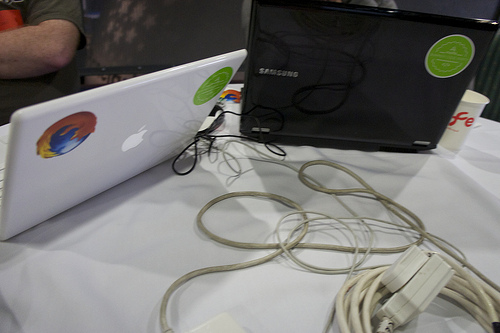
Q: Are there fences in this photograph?
A: No, there are no fences.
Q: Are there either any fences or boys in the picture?
A: No, there are no fences or boys.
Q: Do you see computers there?
A: Yes, there is a computer.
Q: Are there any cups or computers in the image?
A: Yes, there is a computer.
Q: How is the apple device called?
A: The device is a computer.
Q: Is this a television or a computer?
A: This is a computer.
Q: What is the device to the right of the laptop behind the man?
A: The device is a computer.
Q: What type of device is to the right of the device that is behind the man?
A: The device is a computer.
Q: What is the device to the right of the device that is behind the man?
A: The device is a computer.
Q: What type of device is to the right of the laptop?
A: The device is a computer.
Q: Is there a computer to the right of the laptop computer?
A: Yes, there is a computer to the right of the laptop computer.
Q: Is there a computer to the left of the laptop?
A: No, the computer is to the right of the laptop.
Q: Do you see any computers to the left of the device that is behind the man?
A: No, the computer is to the right of the laptop.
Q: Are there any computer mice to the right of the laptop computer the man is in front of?
A: No, there is a computer to the right of the laptop.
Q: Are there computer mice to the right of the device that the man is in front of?
A: No, there is a computer to the right of the laptop.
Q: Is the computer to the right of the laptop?
A: Yes, the computer is to the right of the laptop.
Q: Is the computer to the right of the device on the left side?
A: Yes, the computer is to the right of the laptop.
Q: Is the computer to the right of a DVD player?
A: No, the computer is to the right of the laptop.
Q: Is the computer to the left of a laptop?
A: No, the computer is to the right of a laptop.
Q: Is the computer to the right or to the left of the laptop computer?
A: The computer is to the right of the laptop computer.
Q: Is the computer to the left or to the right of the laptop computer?
A: The computer is to the right of the laptop computer.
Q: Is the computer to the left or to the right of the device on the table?
A: The computer is to the right of the laptop computer.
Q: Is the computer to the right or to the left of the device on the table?
A: The computer is to the right of the laptop computer.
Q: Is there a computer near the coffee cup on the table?
A: Yes, there is a computer near the coffee cup.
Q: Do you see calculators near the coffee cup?
A: No, there is a computer near the coffee cup.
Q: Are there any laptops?
A: Yes, there is a laptop.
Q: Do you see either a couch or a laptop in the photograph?
A: Yes, there is a laptop.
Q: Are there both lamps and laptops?
A: No, there is a laptop but no lamps.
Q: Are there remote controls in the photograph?
A: No, there are no remote controls.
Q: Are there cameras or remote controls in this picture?
A: No, there are no remote controls or cameras.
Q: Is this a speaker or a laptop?
A: This is a laptop.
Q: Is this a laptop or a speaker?
A: This is a laptop.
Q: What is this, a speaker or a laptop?
A: This is a laptop.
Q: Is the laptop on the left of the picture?
A: Yes, the laptop is on the left of the image.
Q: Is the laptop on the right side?
A: No, the laptop is on the left of the image.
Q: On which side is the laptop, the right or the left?
A: The laptop is on the left of the image.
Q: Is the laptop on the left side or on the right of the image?
A: The laptop is on the left of the image.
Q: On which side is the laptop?
A: The laptop is on the left of the image.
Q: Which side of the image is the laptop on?
A: The laptop is on the left of the image.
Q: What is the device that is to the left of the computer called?
A: The device is a laptop.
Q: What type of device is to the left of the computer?
A: The device is a laptop.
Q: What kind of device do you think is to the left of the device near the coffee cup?
A: The device is a laptop.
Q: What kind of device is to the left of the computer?
A: The device is a laptop.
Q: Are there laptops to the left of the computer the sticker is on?
A: Yes, there is a laptop to the left of the computer.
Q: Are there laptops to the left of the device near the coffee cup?
A: Yes, there is a laptop to the left of the computer.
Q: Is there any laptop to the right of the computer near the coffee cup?
A: No, the laptop is to the left of the computer.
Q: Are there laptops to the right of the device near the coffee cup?
A: No, the laptop is to the left of the computer.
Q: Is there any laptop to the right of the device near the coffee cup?
A: No, the laptop is to the left of the computer.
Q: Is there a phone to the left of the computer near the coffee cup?
A: No, there is a laptop to the left of the computer.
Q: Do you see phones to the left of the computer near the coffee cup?
A: No, there is a laptop to the left of the computer.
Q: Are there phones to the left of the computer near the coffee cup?
A: No, there is a laptop to the left of the computer.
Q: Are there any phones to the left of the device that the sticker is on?
A: No, there is a laptop to the left of the computer.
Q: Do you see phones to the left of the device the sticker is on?
A: No, there is a laptop to the left of the computer.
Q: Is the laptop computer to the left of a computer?
A: Yes, the laptop computer is to the left of a computer.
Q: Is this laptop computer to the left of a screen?
A: No, the laptop computer is to the left of a computer.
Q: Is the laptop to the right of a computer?
A: No, the laptop is to the left of a computer.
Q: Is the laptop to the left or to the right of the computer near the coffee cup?
A: The laptop is to the left of the computer.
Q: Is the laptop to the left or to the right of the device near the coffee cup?
A: The laptop is to the left of the computer.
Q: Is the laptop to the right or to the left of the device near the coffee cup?
A: The laptop is to the left of the computer.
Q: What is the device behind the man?
A: The device is a laptop.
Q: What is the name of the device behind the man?
A: The device is a laptop.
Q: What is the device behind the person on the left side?
A: The device is a laptop.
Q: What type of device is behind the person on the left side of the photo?
A: The device is a laptop.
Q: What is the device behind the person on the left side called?
A: The device is a laptop.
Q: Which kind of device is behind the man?
A: The device is a laptop.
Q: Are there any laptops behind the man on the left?
A: Yes, there is a laptop behind the man.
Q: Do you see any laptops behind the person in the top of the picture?
A: Yes, there is a laptop behind the man.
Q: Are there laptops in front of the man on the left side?
A: No, the laptop is behind the man.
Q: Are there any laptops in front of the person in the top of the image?
A: No, the laptop is behind the man.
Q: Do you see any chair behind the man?
A: No, there is a laptop behind the man.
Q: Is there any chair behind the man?
A: No, there is a laptop behind the man.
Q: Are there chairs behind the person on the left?
A: No, there is a laptop behind the man.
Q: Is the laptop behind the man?
A: Yes, the laptop is behind the man.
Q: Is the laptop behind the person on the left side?
A: Yes, the laptop is behind the man.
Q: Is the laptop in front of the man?
A: No, the laptop is behind the man.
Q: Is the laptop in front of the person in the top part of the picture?
A: No, the laptop is behind the man.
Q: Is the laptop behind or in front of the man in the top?
A: The laptop is behind the man.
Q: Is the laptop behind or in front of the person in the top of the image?
A: The laptop is behind the man.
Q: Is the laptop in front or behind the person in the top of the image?
A: The laptop is behind the man.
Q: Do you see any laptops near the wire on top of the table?
A: Yes, there is a laptop near the wire.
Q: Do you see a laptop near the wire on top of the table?
A: Yes, there is a laptop near the wire.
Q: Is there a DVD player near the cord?
A: No, there is a laptop near the cord.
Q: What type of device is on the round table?
A: The device is a laptop.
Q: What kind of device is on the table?
A: The device is a laptop.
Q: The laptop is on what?
A: The laptop is on the table.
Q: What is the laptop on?
A: The laptop is on the table.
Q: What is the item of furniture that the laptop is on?
A: The piece of furniture is a table.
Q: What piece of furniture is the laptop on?
A: The laptop is on the table.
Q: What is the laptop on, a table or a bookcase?
A: The laptop is on a table.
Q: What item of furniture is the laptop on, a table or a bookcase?
A: The laptop is on a table.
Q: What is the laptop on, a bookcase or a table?
A: The laptop is on a table.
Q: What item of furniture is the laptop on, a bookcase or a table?
A: The laptop is on a table.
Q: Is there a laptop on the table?
A: Yes, there is a laptop on the table.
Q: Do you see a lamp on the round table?
A: No, there is a laptop on the table.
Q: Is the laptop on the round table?
A: Yes, the laptop is on the table.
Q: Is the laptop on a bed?
A: No, the laptop is on the table.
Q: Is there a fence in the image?
A: No, there are no fences.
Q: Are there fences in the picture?
A: No, there are no fences.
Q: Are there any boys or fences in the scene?
A: No, there are no fences or boys.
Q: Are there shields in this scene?
A: No, there are no shields.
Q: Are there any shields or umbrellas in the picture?
A: No, there are no shields or umbrellas.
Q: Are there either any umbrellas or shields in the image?
A: No, there are no shields or umbrellas.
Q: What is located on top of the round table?
A: The cord is on top of the table.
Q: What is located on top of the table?
A: The cord is on top of the table.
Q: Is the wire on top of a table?
A: Yes, the wire is on top of a table.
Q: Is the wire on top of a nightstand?
A: No, the wire is on top of a table.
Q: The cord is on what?
A: The cord is on the table.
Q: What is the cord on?
A: The cord is on the table.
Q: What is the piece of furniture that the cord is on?
A: The piece of furniture is a table.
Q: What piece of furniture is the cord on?
A: The cord is on the table.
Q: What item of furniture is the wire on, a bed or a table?
A: The wire is on a table.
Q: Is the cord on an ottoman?
A: No, the cord is on the table.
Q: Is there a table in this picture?
A: Yes, there is a table.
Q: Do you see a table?
A: Yes, there is a table.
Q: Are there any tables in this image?
A: Yes, there is a table.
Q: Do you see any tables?
A: Yes, there is a table.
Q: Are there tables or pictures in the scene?
A: Yes, there is a table.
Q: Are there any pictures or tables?
A: Yes, there is a table.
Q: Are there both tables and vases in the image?
A: No, there is a table but no vases.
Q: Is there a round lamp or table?
A: Yes, there is a round table.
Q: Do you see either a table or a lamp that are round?
A: Yes, the table is round.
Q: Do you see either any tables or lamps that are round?
A: Yes, the table is round.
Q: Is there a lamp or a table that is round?
A: Yes, the table is round.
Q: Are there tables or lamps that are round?
A: Yes, the table is round.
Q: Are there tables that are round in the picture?
A: Yes, there is a round table.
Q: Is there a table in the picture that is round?
A: Yes, there is a table that is round.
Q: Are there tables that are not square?
A: Yes, there is a round table.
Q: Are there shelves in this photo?
A: No, there are no shelves.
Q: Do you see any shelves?
A: No, there are no shelves.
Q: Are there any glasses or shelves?
A: No, there are no shelves or glasses.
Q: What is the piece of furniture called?
A: The piece of furniture is a table.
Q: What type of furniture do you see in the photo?
A: The furniture is a table.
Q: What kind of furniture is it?
A: The piece of furniture is a table.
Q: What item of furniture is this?
A: This is a table.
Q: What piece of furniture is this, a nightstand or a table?
A: This is a table.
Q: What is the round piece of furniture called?
A: The piece of furniture is a table.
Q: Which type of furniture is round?
A: The furniture is a table.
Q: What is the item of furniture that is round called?
A: The piece of furniture is a table.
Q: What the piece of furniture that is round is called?
A: The piece of furniture is a table.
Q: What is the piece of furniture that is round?
A: The piece of furniture is a table.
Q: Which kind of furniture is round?
A: The furniture is a table.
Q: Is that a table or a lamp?
A: That is a table.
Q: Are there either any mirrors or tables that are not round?
A: No, there is a table but it is round.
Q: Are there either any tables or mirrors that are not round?
A: No, there is a table but it is round.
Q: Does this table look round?
A: Yes, the table is round.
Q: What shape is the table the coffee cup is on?
A: The table is round.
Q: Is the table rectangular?
A: No, the table is round.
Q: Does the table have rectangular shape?
A: No, the table is round.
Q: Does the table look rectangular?
A: No, the table is round.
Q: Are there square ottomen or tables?
A: No, there is a table but it is round.